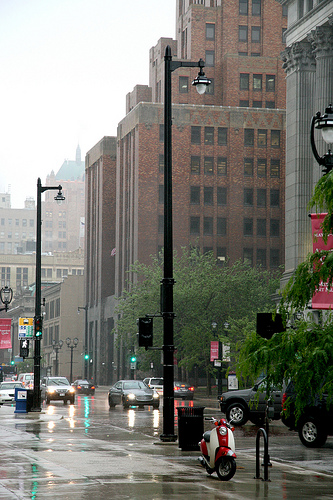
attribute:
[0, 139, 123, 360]
buildings — misty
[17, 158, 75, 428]
lamp — tall, street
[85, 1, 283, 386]
building — tall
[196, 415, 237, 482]
motorbike — parked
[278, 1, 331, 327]
building — grey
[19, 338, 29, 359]
crossing signal — pedestrian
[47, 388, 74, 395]
headlights — on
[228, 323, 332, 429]
branches — tree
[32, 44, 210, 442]
posts — tall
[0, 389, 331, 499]
ground — wet, reflective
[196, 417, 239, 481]
scooter — parked, white, red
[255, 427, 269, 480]
barrier — black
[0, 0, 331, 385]
buildings — array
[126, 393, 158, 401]
headlights — on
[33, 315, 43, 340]
traffic light — mounted, green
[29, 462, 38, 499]
reflection — green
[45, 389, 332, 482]
road — for vehicles, wet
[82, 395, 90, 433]
light — green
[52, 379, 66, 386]
windshield wipers — black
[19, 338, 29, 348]
pedstrian signal — on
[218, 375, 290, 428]
suv — turning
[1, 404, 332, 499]
sidewalk — reflective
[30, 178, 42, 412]
post — tall, black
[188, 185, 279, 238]
windows — dark